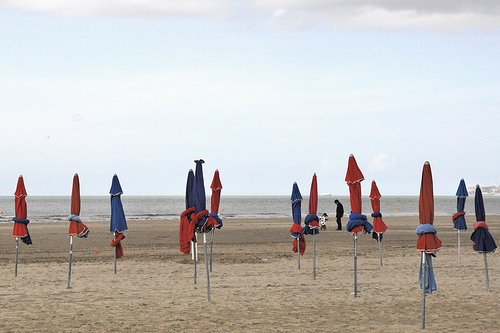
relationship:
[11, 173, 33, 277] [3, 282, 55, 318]
umbrella in sand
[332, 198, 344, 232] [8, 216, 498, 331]
man on sand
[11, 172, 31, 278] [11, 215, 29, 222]
umbrella with strap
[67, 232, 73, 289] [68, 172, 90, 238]
silver pole of umbrella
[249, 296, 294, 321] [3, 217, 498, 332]
sand at beach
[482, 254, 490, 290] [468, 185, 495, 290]
pole for umbrella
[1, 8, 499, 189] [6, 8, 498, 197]
clouds in sky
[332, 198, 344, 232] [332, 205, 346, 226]
man dressed in clothes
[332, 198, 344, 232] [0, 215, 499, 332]
man on sand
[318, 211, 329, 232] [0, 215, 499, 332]
child on sand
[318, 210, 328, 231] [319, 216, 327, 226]
child wearing coat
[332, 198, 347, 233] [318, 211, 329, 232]
man and child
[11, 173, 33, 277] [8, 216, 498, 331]
umbrella in sand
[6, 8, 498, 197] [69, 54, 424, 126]
sky with clouds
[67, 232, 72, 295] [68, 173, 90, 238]
silver pole holding umbrellas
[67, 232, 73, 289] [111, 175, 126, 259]
silver pole holding umbrellas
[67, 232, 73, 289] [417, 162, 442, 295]
silver pole holding umbrellas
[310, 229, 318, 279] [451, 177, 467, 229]
silver pole holding umbrellas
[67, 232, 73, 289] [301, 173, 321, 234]
silver pole holding umbrellas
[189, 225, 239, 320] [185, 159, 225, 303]
pole for umbrella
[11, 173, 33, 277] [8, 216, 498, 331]
umbrella on sand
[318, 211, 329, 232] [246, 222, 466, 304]
child on sand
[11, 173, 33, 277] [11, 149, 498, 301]
umbrella folded on beach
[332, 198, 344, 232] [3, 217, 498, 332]
man standing on beach